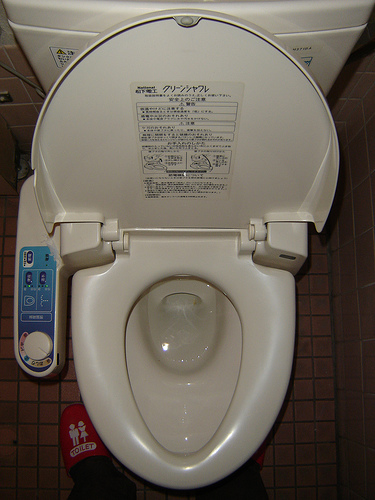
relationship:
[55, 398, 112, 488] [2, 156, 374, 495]
cup on floor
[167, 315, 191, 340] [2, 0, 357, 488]
water in toliet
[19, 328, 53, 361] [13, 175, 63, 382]
button on arm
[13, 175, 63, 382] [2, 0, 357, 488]
arm of toliet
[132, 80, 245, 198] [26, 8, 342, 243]
sticker on back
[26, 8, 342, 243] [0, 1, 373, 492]
back of toilet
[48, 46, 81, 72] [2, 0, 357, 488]
label on toliet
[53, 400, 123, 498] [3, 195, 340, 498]
shoe on floor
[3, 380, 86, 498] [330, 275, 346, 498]
floor with lines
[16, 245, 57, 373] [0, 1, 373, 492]
controls for toilet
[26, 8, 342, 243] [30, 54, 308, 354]
back on toilet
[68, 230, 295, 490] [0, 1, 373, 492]
seat on toilet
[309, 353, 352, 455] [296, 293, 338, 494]
tile on floor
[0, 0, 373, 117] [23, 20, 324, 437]
tank behind toilet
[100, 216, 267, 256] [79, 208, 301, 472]
hinges on lid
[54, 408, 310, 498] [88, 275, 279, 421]
person front toilet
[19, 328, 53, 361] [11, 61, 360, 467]
button next toilet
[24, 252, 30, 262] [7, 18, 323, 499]
button on toilet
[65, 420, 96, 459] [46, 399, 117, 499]
toilet symbol on cup